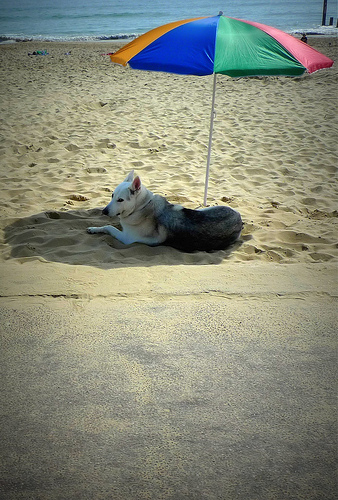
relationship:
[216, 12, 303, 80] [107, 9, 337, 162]
stripe on umbrella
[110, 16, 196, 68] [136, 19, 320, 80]
stripe on umbrella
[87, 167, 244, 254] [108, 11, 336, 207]
dog under umbrella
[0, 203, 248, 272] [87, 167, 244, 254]
shadow of dog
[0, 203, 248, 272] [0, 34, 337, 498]
shadow in sand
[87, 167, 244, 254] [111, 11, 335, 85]
dog under umbrella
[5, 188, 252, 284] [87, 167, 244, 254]
shadow of dog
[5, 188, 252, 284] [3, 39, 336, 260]
shadow on sand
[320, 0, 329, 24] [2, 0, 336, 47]
black post in water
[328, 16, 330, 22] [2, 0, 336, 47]
black post in water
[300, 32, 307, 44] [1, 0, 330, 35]
person near water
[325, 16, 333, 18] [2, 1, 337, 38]
stick in water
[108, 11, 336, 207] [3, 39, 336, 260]
umbrella on sand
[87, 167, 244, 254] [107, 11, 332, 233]
dog lies under umbrella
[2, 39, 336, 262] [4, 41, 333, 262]
sands on beach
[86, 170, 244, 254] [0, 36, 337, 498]
dog at beach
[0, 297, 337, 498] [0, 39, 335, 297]
pavement near beach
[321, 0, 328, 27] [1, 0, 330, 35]
black post sticks out of water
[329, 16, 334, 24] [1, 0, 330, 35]
black post sticks out of water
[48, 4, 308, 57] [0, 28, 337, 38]
waves come into shore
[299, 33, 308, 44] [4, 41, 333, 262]
person on beach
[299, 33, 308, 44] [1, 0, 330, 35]
person near water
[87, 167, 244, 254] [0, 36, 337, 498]
dog lays on beach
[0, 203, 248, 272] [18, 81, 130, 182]
shadow on sand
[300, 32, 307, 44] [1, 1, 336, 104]
person in background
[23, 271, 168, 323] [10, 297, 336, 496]
sand on concrete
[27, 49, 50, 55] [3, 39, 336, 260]
object in sand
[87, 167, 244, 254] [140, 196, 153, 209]
dog wears collar